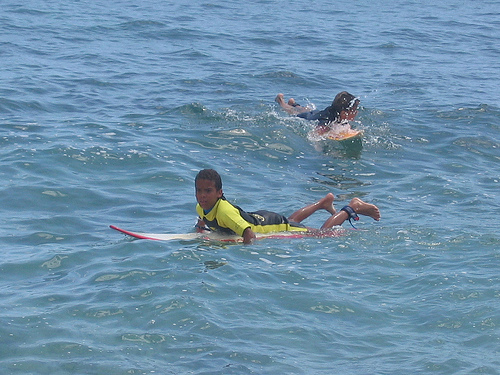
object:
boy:
[193, 167, 380, 245]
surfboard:
[107, 223, 340, 244]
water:
[0, 0, 498, 374]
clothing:
[293, 106, 337, 127]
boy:
[274, 91, 360, 139]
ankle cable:
[339, 204, 359, 232]